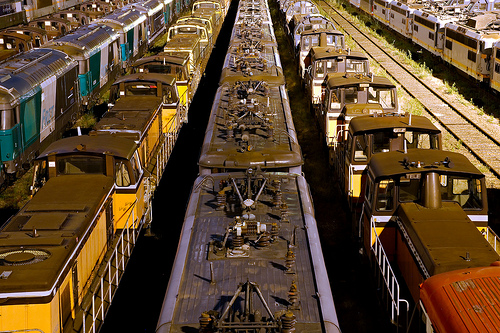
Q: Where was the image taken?
A: It was taken at the yard.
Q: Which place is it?
A: It is a yard.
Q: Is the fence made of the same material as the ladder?
A: Yes, both the fence and the ladder are made of metal.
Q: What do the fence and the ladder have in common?
A: The material, both the fence and the ladder are metallic.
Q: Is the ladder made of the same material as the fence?
A: Yes, both the ladder and the fence are made of metal.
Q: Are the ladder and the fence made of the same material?
A: Yes, both the ladder and the fence are made of metal.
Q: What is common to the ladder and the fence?
A: The material, both the ladder and the fence are metallic.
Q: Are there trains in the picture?
A: Yes, there is a train.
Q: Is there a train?
A: Yes, there is a train.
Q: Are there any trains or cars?
A: Yes, there is a train.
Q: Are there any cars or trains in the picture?
A: Yes, there is a train.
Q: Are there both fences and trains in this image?
A: Yes, there are both a train and a fence.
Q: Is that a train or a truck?
A: That is a train.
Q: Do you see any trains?
A: Yes, there is a train.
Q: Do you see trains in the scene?
A: Yes, there is a train.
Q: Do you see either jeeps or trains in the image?
A: Yes, there is a train.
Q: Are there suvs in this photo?
A: No, there are no suvs.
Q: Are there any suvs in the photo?
A: No, there are no suvs.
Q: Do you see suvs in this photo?
A: No, there are no suvs.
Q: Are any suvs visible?
A: No, there are no suvs.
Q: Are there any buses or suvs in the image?
A: No, there are no suvs or buses.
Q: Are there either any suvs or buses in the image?
A: No, there are no suvs or buses.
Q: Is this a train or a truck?
A: This is a train.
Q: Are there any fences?
A: Yes, there is a fence.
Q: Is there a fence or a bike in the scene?
A: Yes, there is a fence.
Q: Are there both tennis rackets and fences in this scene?
A: No, there is a fence but no rackets.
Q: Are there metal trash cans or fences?
A: Yes, there is a metal fence.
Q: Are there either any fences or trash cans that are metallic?
A: Yes, the fence is metallic.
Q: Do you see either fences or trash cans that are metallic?
A: Yes, the fence is metallic.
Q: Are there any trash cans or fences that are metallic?
A: Yes, the fence is metallic.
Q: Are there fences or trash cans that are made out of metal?
A: Yes, the fence is made of metal.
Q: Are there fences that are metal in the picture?
A: Yes, there is a metal fence.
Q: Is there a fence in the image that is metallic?
A: Yes, there is a fence that is metallic.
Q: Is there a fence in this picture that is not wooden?
A: Yes, there is a metallic fence.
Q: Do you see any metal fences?
A: Yes, there is a fence that is made of metal.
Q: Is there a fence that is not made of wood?
A: Yes, there is a fence that is made of metal.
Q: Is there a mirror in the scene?
A: No, there are no mirrors.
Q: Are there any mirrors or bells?
A: No, there are no mirrors or bells.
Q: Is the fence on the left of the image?
A: Yes, the fence is on the left of the image.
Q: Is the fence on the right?
A: No, the fence is on the left of the image.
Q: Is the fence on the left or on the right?
A: The fence is on the left of the image.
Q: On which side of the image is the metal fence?
A: The fence is on the left of the image.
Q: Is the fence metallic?
A: Yes, the fence is metallic.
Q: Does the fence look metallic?
A: Yes, the fence is metallic.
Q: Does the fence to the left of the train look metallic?
A: Yes, the fence is metallic.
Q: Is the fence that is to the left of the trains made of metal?
A: Yes, the fence is made of metal.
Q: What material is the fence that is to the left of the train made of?
A: The fence is made of metal.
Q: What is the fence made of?
A: The fence is made of metal.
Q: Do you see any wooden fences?
A: No, there is a fence but it is metallic.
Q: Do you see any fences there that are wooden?
A: No, there is a fence but it is metallic.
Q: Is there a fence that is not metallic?
A: No, there is a fence but it is metallic.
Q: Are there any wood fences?
A: No, there is a fence but it is made of metal.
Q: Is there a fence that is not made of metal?
A: No, there is a fence but it is made of metal.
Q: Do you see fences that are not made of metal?
A: No, there is a fence but it is made of metal.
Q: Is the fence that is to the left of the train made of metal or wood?
A: The fence is made of metal.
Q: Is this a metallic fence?
A: Yes, this is a metallic fence.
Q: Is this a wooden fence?
A: No, this is a metallic fence.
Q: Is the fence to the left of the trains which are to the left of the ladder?
A: Yes, the fence is to the left of the trains.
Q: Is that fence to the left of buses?
A: No, the fence is to the left of the trains.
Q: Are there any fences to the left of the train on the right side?
A: Yes, there is a fence to the left of the train.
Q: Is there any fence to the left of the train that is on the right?
A: Yes, there is a fence to the left of the train.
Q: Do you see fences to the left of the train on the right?
A: Yes, there is a fence to the left of the train.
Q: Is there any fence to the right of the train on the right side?
A: No, the fence is to the left of the train.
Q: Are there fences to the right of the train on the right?
A: No, the fence is to the left of the train.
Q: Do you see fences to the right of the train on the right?
A: No, the fence is to the left of the train.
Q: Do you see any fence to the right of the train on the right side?
A: No, the fence is to the left of the train.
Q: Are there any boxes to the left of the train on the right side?
A: No, there is a fence to the left of the train.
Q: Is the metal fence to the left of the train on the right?
A: Yes, the fence is to the left of the train.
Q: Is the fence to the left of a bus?
A: No, the fence is to the left of the train.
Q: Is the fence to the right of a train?
A: No, the fence is to the left of a train.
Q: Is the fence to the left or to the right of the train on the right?
A: The fence is to the left of the train.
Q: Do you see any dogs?
A: No, there are no dogs.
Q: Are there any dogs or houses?
A: No, there are no dogs or houses.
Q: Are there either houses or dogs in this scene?
A: No, there are no dogs or houses.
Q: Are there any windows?
A: Yes, there is a window.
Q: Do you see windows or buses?
A: Yes, there is a window.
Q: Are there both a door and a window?
A: No, there is a window but no doors.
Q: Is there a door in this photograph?
A: No, there are no doors.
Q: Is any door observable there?
A: No, there are no doors.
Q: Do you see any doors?
A: No, there are no doors.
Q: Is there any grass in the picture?
A: Yes, there is grass.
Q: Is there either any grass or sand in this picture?
A: Yes, there is grass.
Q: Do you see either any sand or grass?
A: Yes, there is grass.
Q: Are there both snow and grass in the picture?
A: No, there is grass but no snow.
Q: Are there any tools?
A: No, there are no tools.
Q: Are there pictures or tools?
A: No, there are no tools or pictures.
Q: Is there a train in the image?
A: Yes, there are trains.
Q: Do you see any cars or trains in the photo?
A: Yes, there are trains.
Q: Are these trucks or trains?
A: These are trains.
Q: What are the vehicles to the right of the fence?
A: The vehicles are trains.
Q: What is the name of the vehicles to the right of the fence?
A: The vehicles are trains.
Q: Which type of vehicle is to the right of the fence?
A: The vehicles are trains.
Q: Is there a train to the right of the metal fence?
A: Yes, there are trains to the right of the fence.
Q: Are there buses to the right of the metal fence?
A: No, there are trains to the right of the fence.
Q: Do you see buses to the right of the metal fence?
A: No, there are trains to the right of the fence.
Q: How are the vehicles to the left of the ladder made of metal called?
A: The vehicles are trains.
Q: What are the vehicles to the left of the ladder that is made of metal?
A: The vehicles are trains.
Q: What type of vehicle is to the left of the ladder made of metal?
A: The vehicles are trains.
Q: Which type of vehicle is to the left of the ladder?
A: The vehicles are trains.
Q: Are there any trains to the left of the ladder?
A: Yes, there are trains to the left of the ladder.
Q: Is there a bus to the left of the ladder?
A: No, there are trains to the left of the ladder.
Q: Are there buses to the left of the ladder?
A: No, there are trains to the left of the ladder.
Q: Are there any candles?
A: No, there are no candles.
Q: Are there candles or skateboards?
A: No, there are no candles or skateboards.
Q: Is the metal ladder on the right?
A: Yes, the ladder is on the right of the image.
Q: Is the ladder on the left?
A: No, the ladder is on the right of the image.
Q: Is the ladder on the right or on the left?
A: The ladder is on the right of the image.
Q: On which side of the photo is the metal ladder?
A: The ladder is on the right of the image.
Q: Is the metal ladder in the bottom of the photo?
A: Yes, the ladder is in the bottom of the image.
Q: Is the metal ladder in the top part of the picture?
A: No, the ladder is in the bottom of the image.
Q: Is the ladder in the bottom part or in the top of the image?
A: The ladder is in the bottom of the image.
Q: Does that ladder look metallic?
A: Yes, the ladder is metallic.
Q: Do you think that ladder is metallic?
A: Yes, the ladder is metallic.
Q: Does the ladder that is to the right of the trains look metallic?
A: Yes, the ladder is metallic.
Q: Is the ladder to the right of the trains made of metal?
A: Yes, the ladder is made of metal.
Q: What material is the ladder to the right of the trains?
A: The ladder is made of metal.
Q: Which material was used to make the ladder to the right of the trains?
A: The ladder is made of metal.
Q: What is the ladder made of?
A: The ladder is made of metal.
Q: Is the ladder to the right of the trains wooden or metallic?
A: The ladder is metallic.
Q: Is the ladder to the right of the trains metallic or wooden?
A: The ladder is metallic.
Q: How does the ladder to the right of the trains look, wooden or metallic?
A: The ladder is metallic.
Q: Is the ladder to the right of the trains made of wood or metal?
A: The ladder is made of metal.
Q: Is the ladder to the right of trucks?
A: No, the ladder is to the right of the trains.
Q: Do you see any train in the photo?
A: Yes, there is a train.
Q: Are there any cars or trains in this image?
A: Yes, there is a train.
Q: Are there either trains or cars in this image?
A: Yes, there is a train.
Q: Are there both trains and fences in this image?
A: Yes, there are both a train and a fence.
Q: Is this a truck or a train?
A: This is a train.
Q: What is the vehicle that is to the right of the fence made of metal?
A: The vehicle is a train.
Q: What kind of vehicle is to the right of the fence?
A: The vehicle is a train.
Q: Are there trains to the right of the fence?
A: Yes, there is a train to the right of the fence.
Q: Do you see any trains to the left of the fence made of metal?
A: No, the train is to the right of the fence.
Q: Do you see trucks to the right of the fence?
A: No, there is a train to the right of the fence.